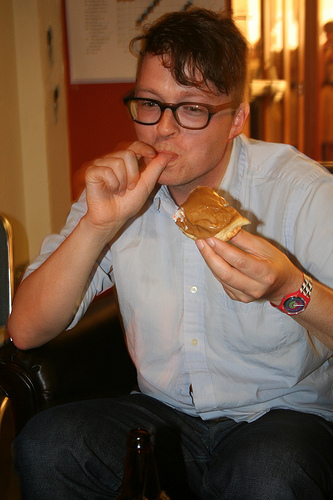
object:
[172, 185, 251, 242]
doughnut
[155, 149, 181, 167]
mouth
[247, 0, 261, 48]
light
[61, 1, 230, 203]
wall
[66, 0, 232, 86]
board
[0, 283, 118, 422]
chair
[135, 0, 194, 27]
crossword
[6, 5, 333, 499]
man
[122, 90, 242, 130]
glasses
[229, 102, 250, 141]
ear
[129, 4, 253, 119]
hair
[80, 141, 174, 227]
hand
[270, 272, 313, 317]
watch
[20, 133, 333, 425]
shirt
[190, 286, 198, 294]
button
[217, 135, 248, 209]
collar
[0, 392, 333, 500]
pants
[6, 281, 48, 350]
elbow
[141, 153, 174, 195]
thumb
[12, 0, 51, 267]
wall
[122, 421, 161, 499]
bottle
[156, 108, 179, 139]
nose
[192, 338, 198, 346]
button